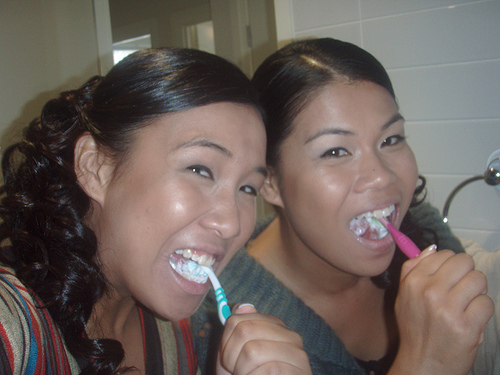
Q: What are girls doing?
A: Brushing their teeth.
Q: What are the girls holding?
A: Toothbrush.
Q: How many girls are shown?
A: Two.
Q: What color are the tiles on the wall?
A: White.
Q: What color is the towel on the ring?
A: White.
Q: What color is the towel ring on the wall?
A: Silver.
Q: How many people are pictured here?
A: Two.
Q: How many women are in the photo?
A: Two.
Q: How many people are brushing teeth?
A: Two.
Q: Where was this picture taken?
A: Bathroom.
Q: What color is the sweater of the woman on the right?
A: Grey.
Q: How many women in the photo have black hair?
A: Two.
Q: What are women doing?
A: Brushing teeth.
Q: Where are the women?
A: In a bathroom.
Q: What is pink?
A: Toothbrush on right.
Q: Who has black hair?
A: Two women.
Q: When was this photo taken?
A: Probably in the morning or evening.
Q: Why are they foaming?
A: Toothpaste.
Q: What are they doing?
A: Brushing their teeth.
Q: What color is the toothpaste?
A: Light blue.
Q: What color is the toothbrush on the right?
A: Pink.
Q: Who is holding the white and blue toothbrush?
A: The girl on the left.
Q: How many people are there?
A: Two.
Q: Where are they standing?
A: In a bathroom.